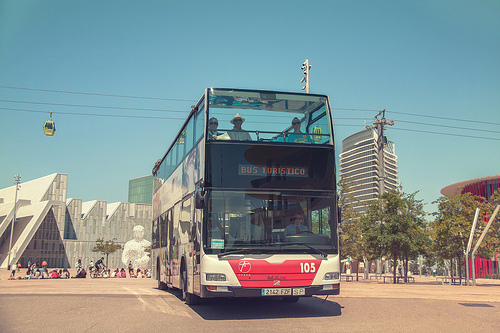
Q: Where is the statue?
A: Behind the bus.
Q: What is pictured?
A: A bus.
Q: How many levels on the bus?
A: Two.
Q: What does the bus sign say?
A: Bus turistico.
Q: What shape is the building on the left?
A: Triangle.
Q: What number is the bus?
A: 105.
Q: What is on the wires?
A: Gondolas.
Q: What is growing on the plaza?
A: Trees.